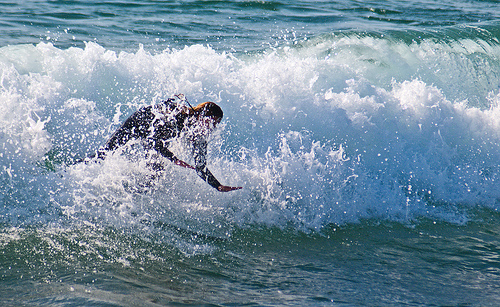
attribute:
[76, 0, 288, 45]
water — clear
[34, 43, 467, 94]
wave — big, rolling, splasing, blue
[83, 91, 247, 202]
person — leaning, surfing, turned right